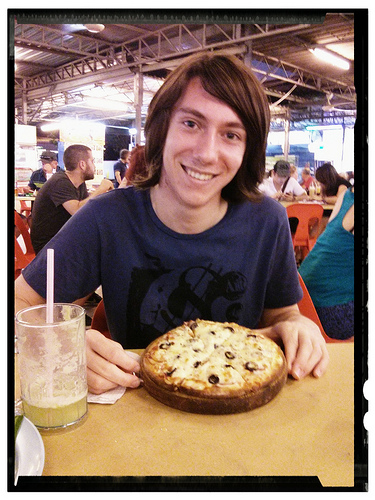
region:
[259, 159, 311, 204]
A person wearing a hat.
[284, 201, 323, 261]
A empty orange chair.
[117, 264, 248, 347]
A black design on a shirt.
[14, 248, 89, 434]
A cup with a straw in it.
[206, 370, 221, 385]
A black olive on a pizza.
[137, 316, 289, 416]
A pizza on a table.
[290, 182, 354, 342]
A person in a turquoise shirt.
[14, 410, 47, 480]
Corner of a plate.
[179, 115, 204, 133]
Eye on a person.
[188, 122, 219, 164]
Nose on a person.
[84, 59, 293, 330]
A person seated at the table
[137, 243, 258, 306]
Blue t-shirt in the photo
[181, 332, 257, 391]
A pizza on the table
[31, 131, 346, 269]
People seated in a restaurant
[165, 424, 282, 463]
A table in the photo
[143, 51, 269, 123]
Long hair on the head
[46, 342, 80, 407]
A glass in the photo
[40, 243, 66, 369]
A straw on the glass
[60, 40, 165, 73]
Metal railings on the roof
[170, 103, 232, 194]
A person smiling